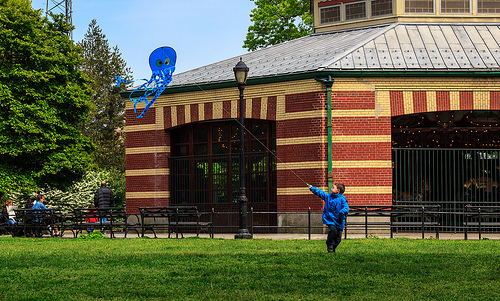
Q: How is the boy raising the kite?
A: By running.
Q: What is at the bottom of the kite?
A: Streamers shaped like tentacles.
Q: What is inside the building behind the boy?
A: A carousel.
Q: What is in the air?
A: Kite.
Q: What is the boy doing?
A: Flying a kite.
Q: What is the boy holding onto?
A: Kite string.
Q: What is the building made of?
A: Brick.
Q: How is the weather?
A: Sunny.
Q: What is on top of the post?
A: Lamp.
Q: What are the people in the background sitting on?
A: Bench.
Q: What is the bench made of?
A: Metal.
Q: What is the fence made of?
A: Metal.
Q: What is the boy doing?
A: Flying a kite.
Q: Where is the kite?
A: Up in the air.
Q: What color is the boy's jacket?
A: Blue.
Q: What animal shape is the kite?
A: An octopus.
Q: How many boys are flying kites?
A: One.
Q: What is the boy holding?
A: A string.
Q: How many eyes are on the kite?
A: Two.